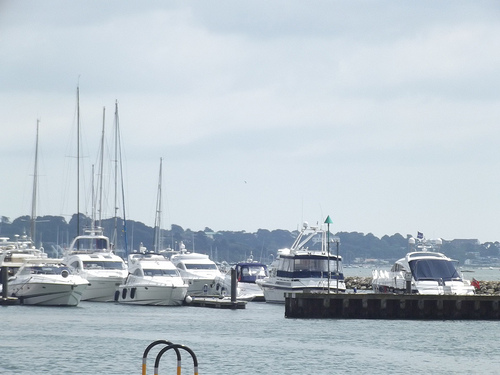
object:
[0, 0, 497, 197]
clouds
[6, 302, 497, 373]
lake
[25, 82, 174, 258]
post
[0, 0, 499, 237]
background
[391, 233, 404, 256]
trees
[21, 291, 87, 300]
stripe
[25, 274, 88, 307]
front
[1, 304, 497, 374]
water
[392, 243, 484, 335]
boat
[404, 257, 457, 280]
front window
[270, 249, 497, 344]
pier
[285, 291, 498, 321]
dock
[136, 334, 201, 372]
hand rail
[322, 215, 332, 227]
triangular object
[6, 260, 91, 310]
boat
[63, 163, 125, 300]
boat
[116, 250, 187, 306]
boat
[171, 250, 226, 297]
boat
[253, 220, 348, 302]
boat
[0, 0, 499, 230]
cloudy sky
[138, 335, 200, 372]
hand rails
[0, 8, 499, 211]
sky clouds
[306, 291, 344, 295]
railing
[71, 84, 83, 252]
mast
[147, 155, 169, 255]
masts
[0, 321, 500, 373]
ripples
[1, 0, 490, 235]
sky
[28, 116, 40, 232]
these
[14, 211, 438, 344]
these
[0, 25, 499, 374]
seen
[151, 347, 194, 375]
portion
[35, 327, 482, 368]
line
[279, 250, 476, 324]
asphalt